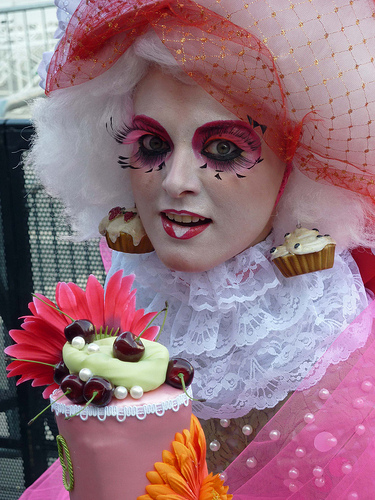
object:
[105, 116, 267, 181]
eyelashes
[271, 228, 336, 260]
frosting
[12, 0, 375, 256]
hair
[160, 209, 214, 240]
lips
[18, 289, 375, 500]
veil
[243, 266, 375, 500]
shoulder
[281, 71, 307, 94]
ground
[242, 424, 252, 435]
white pearl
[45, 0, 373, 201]
net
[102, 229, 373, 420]
collar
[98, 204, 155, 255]
earring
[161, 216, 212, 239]
lips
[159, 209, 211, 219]
lips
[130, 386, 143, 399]
pearl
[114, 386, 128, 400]
pearl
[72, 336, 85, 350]
pearl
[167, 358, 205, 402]
cherry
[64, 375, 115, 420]
cherry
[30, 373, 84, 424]
cherry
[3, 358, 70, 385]
cherry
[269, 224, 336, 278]
cupcake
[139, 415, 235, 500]
flower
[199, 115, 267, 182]
lashes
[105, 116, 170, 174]
lashes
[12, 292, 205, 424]
cherries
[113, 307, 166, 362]
cherry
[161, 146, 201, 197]
nose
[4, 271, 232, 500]
flowers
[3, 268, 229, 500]
costume piece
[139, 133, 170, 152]
eye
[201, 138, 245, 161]
eye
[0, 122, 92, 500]
fence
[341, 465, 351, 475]
beads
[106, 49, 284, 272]
head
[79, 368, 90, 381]
pearl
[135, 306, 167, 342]
stem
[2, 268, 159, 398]
flower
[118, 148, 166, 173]
feathers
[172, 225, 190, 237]
lipstick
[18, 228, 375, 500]
dress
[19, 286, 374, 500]
chiffon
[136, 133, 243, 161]
eyes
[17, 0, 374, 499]
lady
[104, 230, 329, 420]
neck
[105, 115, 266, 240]
makeup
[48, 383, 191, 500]
dish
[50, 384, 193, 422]
surface